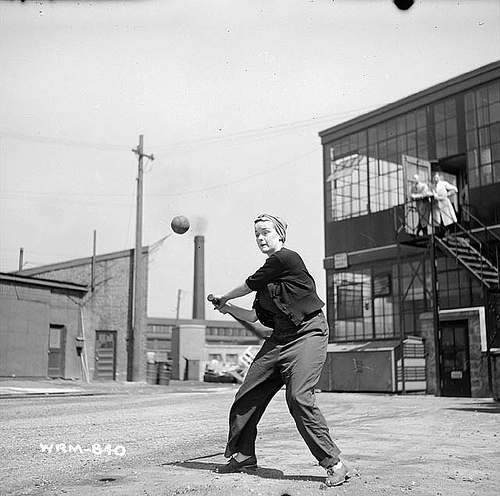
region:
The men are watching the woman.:
[396, 155, 471, 243]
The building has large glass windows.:
[325, 80, 490, 211]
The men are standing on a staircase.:
[382, 135, 482, 300]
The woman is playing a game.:
[165, 195, 372, 492]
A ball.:
[155, 200, 200, 250]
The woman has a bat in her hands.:
[200, 210, 370, 485]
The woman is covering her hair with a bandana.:
[245, 195, 290, 257]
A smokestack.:
[180, 225, 212, 325]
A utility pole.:
[110, 120, 155, 395]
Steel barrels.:
[141, 353, 176, 388]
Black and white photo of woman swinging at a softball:
[5, 0, 498, 493]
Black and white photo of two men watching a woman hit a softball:
[400, 154, 499, 289]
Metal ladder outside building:
[435, 231, 498, 291]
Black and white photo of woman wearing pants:
[220, 320, 345, 466]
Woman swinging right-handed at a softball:
[207, 213, 325, 324]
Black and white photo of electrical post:
[112, 127, 158, 382]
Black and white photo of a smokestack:
[192, 231, 207, 318]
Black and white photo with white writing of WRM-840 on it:
[30, 437, 138, 464]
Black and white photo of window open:
[325, 125, 373, 222]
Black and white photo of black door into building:
[432, 316, 477, 398]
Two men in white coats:
[402, 158, 497, 238]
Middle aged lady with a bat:
[193, 191, 373, 477]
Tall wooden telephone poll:
[116, 116, 166, 387]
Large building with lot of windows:
[312, 68, 498, 405]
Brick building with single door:
[1, 273, 96, 388]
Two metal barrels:
[147, 361, 172, 389]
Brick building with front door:
[71, 255, 147, 385]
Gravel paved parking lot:
[2, 398, 197, 493]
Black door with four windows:
[434, 320, 478, 394]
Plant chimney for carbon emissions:
[184, 225, 225, 317]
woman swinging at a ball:
[211, 210, 353, 485]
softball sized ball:
[166, 215, 193, 234]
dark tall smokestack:
[190, 231, 207, 327]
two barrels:
[143, 355, 175, 386]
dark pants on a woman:
[223, 315, 341, 468]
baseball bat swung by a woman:
[206, 292, 266, 339]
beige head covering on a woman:
[255, 212, 285, 241]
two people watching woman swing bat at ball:
[407, 170, 457, 234]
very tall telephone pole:
[125, 131, 155, 382]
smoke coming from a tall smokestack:
[189, 215, 214, 236]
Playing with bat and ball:
[130, 180, 382, 489]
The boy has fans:
[385, 162, 472, 256]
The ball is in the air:
[137, 182, 257, 282]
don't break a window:
[320, 150, 401, 214]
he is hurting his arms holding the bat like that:
[173, 263, 295, 344]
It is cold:
[207, 205, 372, 485]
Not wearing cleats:
[196, 430, 373, 492]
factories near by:
[189, 225, 211, 329]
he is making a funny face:
[232, 205, 302, 255]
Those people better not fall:
[382, 163, 478, 265]